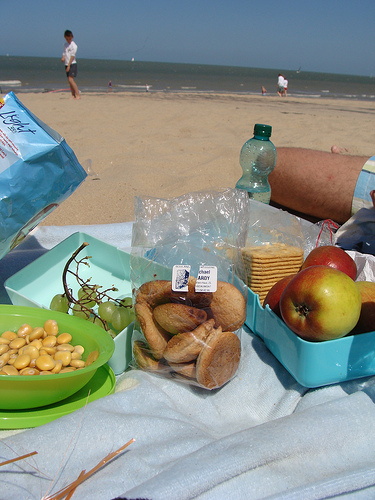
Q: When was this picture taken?
A: During the day.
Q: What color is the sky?
A: Blue.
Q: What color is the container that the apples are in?
A: Blue.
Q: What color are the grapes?
A: Green.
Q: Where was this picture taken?
A: At a beach.